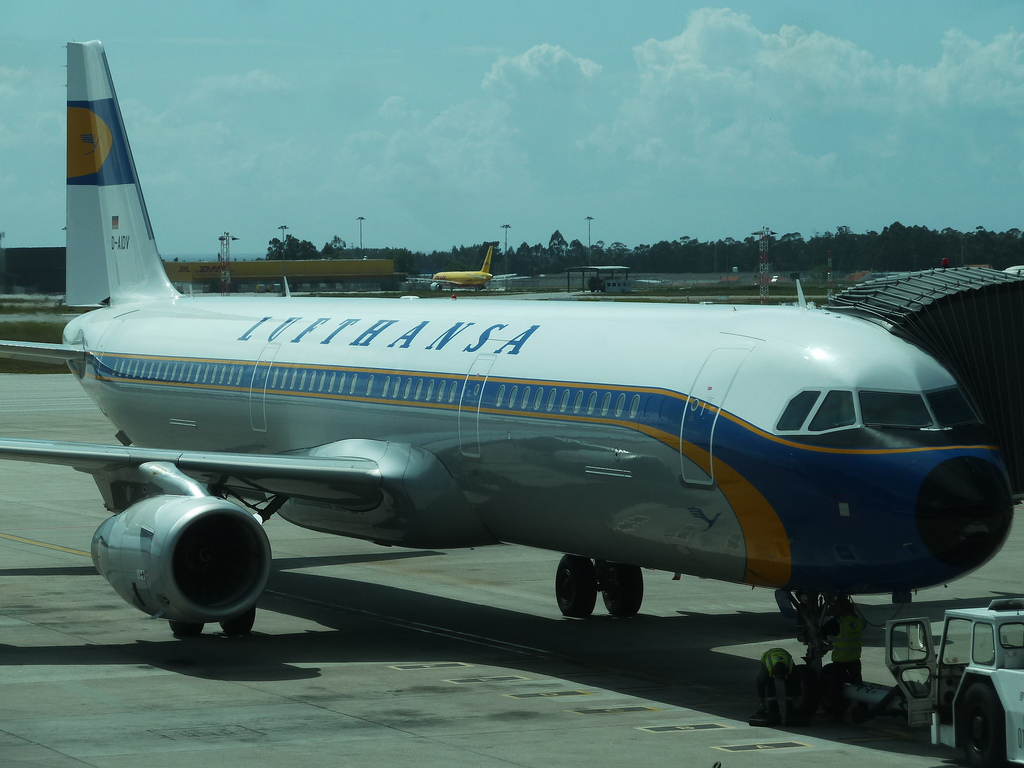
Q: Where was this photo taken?
A: On the tarmac at an airport.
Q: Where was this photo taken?
A: An airport.